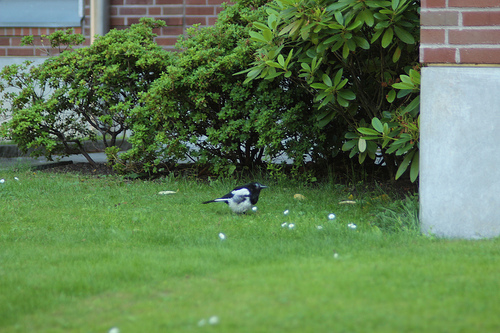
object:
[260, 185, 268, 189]
beak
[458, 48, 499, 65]
bricks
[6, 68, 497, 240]
cement foundation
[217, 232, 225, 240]
white flowers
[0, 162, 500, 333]
grass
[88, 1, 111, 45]
pipe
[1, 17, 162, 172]
bush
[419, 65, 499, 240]
base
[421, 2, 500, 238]
wall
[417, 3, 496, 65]
bricks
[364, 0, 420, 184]
plant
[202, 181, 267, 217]
bird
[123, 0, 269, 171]
trees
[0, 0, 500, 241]
building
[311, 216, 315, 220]
weeds